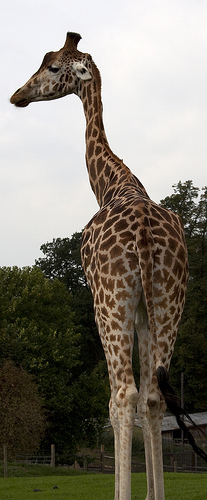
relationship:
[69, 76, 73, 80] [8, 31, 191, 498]
brown spot on giraffe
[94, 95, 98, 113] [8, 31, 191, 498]
brown spot on giraffe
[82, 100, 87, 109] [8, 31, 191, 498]
brown spot on giraffe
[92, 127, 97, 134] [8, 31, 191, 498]
brown spot on giraffe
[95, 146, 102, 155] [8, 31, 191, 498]
brown spot on giraffe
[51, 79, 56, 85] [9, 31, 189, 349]
spot on giraffe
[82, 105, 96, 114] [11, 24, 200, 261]
spot on giraffe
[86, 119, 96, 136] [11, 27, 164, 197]
spot on giraffe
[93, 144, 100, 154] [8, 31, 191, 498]
spot on giraffe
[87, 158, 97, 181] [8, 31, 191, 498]
spot on giraffe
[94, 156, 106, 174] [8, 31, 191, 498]
spot on giraffe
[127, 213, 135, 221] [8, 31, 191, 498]
brown spot on giraffe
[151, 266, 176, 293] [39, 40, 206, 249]
spot on giraffe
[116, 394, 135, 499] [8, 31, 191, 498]
leg of giraffe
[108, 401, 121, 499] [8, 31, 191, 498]
leg of giraffe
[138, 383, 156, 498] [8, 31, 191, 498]
leg of giraffe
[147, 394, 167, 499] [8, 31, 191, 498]
leg of giraffe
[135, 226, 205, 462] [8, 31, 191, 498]
tail of giraffe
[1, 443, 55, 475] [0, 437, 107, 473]
poles forming fence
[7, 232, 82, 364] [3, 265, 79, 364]
tree with leaves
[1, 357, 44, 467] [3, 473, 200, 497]
tree closer ground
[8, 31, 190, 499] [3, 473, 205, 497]
giraffe standing in grass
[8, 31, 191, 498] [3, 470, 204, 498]
giraffe standing up grass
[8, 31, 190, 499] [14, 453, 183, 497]
giraffe standing up grass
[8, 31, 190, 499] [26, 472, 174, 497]
giraffe standing up grass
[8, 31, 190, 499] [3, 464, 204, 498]
giraffe standing up grass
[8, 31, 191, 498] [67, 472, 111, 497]
giraffe stands in grass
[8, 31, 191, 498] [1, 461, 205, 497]
giraffe stands in grass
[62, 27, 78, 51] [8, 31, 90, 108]
ossicone on giraffe head